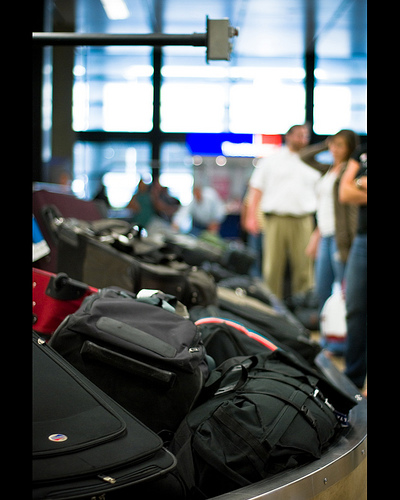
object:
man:
[242, 124, 321, 302]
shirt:
[248, 144, 326, 219]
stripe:
[189, 316, 279, 356]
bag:
[188, 303, 361, 433]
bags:
[33, 332, 176, 499]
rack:
[178, 393, 366, 499]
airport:
[32, 1, 368, 499]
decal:
[46, 424, 71, 451]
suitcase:
[32, 354, 168, 492]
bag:
[168, 352, 345, 497]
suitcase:
[35, 265, 99, 353]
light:
[96, 0, 132, 22]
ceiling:
[72, 0, 365, 32]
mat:
[33, 335, 128, 456]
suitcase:
[48, 290, 212, 447]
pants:
[261, 211, 317, 309]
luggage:
[32, 264, 101, 337]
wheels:
[47, 269, 73, 294]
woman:
[309, 126, 349, 334]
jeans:
[309, 236, 350, 308]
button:
[224, 21, 242, 41]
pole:
[32, 31, 207, 49]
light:
[157, 67, 305, 135]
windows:
[99, 61, 312, 133]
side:
[245, 434, 368, 500]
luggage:
[32, 326, 193, 499]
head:
[283, 124, 313, 153]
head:
[325, 127, 355, 164]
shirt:
[312, 170, 341, 239]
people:
[306, 131, 360, 329]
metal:
[313, 385, 335, 416]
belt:
[237, 366, 331, 413]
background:
[32, 2, 365, 275]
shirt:
[333, 162, 359, 258]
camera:
[206, 14, 239, 65]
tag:
[140, 283, 187, 319]